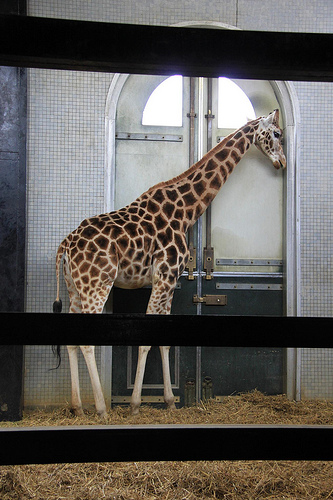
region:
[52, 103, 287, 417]
giraffe standing on tan hay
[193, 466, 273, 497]
patch of tan hay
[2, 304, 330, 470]
black wooden fence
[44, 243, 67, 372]
giraffe tail with dark brown hair at tip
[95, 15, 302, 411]
tall large steel door with locks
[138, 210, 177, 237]
brown and tan spots on giraffe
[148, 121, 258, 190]
brown giraffe mane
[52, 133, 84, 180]
side tiles on front of door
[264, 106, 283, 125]
grey and brown giraffe ossicones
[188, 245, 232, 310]
metal bolt lock on door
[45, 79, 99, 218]
a wall made of small white tiles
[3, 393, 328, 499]
hay on the floor of a giraffe pen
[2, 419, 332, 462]
a wood plank on a fence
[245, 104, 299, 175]
a giraffe resting its head on a door frame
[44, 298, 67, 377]
black hair on a giraffe tail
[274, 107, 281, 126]
a horn on a giraffe head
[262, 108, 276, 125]
an ear on a giraffe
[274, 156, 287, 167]
the mouth of a giraffe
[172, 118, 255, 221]
the longneck of a giraffe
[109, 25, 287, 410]
a door in a giraffe pen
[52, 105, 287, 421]
giraffe standing in hay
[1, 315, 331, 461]
black wooden fence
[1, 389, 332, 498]
hay laying on barn floor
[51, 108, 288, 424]
giraffe standing next to door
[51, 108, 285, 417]
giraffe waiting for food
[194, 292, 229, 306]
brown wooden door latch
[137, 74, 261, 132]
windows in barn door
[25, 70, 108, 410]
tiled barn interior walls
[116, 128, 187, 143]
grey metal door latch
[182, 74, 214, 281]
bronze metal door locks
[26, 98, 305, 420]
The giraffe is in an enclosure.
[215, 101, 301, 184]
The giraffe is sad.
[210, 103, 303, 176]
The giraffe's head leans on the wall.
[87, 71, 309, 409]
The enclosure has a door.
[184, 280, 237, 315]
A bolt is on the door.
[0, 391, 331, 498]
Hay covers the floor.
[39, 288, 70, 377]
The tip of the giraffe's tail is black.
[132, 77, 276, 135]
The door has two windows.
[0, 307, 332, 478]
A fence is in the foreground.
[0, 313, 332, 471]
The fence is black.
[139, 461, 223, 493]
The hay is visible.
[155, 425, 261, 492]
The hay is visible.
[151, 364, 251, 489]
The hay is visible.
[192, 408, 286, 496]
The hay is visible.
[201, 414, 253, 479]
The hay is visible.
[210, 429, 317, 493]
The hay is visible.